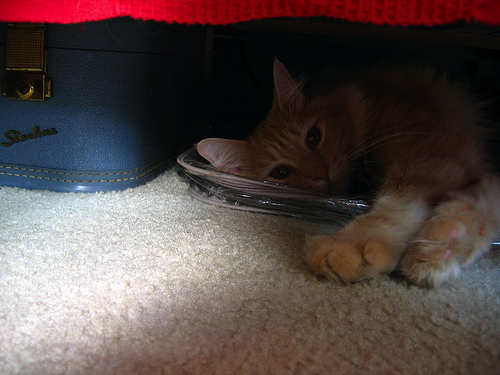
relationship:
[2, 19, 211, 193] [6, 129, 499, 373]
luggage on floor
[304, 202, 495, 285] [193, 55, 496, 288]
paws of cat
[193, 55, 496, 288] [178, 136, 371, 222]
cat on bag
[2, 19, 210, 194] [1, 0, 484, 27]
luggage lying underneath cloth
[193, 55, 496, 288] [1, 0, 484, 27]
cat lying underneath cloth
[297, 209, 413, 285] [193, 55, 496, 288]
paw belonging to cat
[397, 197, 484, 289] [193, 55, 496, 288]
paw belonging to cat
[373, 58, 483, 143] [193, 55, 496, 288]
body belonging to cat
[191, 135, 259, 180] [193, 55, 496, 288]
ear belonging to cat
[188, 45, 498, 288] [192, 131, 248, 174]
cat has ear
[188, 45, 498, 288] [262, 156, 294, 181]
cat has eye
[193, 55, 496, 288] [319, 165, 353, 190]
cat has mouth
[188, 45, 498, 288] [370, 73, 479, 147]
cat has hair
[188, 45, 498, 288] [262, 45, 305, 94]
cat has ear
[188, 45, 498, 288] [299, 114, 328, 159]
cat has eye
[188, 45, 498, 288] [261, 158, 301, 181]
cat has eye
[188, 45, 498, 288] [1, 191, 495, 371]
cat on carpet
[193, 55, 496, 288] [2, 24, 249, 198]
cat by luggage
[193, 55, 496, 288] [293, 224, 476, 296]
cat has paws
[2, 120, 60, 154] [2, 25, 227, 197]
word on suitcase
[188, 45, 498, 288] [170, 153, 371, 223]
cat on plastic